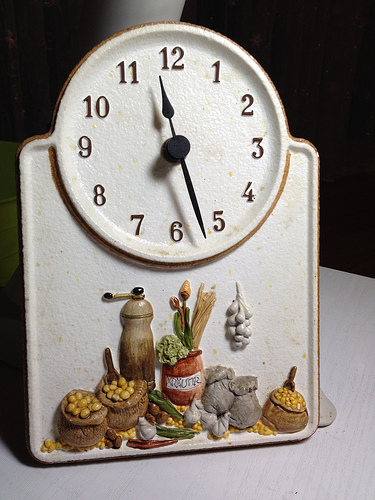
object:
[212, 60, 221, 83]
digit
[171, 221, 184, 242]
digit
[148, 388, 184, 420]
green bean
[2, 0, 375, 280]
form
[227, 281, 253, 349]
garlic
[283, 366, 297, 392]
spoon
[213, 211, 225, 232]
digit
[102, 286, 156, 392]
pepper grinder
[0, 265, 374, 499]
table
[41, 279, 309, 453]
design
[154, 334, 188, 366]
vegetable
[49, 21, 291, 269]
clock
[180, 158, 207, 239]
black hand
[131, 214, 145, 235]
digit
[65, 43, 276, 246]
face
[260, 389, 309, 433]
bag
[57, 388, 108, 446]
bag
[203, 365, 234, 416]
sack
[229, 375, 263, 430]
sack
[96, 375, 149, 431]
bag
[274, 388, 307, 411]
food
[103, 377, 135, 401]
food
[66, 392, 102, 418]
food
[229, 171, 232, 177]
speck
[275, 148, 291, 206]
trim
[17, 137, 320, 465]
panel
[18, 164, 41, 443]
edge